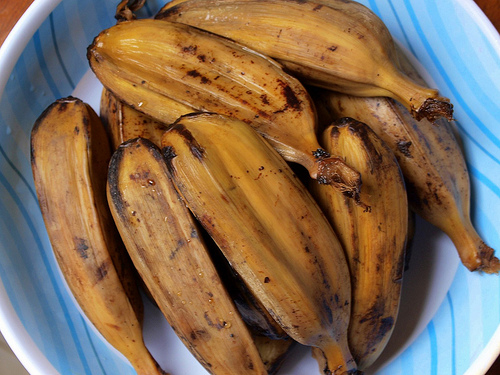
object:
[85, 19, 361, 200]
bananas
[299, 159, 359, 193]
stalk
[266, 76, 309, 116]
patches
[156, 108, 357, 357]
peel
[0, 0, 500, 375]
table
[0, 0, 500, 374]
bowl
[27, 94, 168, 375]
plantains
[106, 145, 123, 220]
black spots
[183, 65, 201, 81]
brown spot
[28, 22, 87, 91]
paint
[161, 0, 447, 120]
fruit